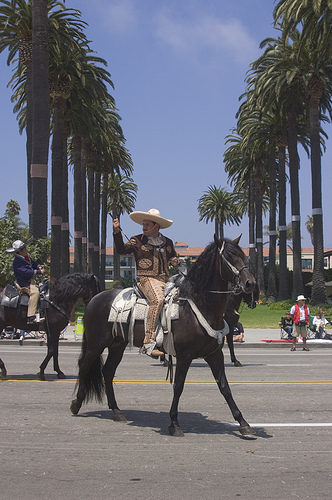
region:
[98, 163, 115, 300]
The tree trunk is straight.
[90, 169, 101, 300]
The tree trunk is straight.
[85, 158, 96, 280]
The tree trunk is straight.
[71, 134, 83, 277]
The tree trunk is straight.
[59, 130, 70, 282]
The tree trunk is straight.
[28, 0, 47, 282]
The tree trunk is straight.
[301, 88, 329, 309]
The tree trunk is straight.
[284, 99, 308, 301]
The tree trunk is straight.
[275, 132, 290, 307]
The tree trunk is straight.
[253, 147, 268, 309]
The tree trunk is straight.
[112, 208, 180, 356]
the man on the horse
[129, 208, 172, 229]
the hat on the man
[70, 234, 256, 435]
the horse the man is on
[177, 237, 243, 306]
the mane on the horse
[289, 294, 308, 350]
the man standing on the road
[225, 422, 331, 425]
the white line near the horse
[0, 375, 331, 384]
the yellow lines on the road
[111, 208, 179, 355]
the man on the horse wearing brown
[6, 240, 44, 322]
the man on the horse wearing a blue jacket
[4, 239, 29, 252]
the hat on the man wearing a blue jacket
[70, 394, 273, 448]
shadow of the horse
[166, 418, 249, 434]
hooves of the horse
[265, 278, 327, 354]
people on the sidewalk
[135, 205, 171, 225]
hat on the head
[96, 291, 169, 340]
saddle on the horse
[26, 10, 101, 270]
the trees are palm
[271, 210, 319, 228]
paint on the trees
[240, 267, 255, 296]
snout of the horse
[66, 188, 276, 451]
man riding a horse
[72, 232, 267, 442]
a dark brown horse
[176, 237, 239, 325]
black mane on horse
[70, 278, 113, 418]
black tail of horse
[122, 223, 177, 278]
man wearing brown top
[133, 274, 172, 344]
man wearing light brown pants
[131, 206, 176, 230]
man wearing a sombrero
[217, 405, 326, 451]
a white line on street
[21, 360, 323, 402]
a yellow line on street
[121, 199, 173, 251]
the head of a man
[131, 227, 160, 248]
the chin of a man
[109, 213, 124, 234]
the hand of a man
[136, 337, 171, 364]
the foot of a man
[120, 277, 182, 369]
the leg of a man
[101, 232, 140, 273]
the elbow of a man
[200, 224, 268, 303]
the head of a horse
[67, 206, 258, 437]
Man riding a horse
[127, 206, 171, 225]
Straw hat on man's head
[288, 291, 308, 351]
Man standing in front of the curb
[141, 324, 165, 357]
Man's foot in the stirrup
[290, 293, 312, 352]
man standing by the curb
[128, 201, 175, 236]
man is wearing a sombero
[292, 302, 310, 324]
man is wearing a red vest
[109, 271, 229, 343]
horse has a white saddle and blanket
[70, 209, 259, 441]
man riding a horse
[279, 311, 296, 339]
boy sitting in a portable chair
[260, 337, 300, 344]
red towel on the sidewalk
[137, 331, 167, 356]
man's foot is in the stirup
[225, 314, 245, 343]
person sitting on the sidewalk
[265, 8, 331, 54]
tree near a street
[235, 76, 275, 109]
tree near a street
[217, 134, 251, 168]
tree near a street